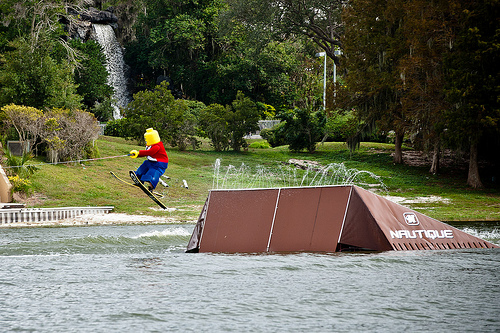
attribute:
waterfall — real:
[95, 24, 132, 121]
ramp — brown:
[187, 185, 498, 253]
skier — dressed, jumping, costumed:
[129, 125, 169, 193]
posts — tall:
[318, 50, 327, 110]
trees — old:
[0, 4, 499, 185]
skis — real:
[129, 171, 167, 209]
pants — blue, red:
[135, 162, 168, 189]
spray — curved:
[211, 158, 388, 191]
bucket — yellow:
[142, 126, 162, 146]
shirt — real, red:
[141, 144, 169, 161]